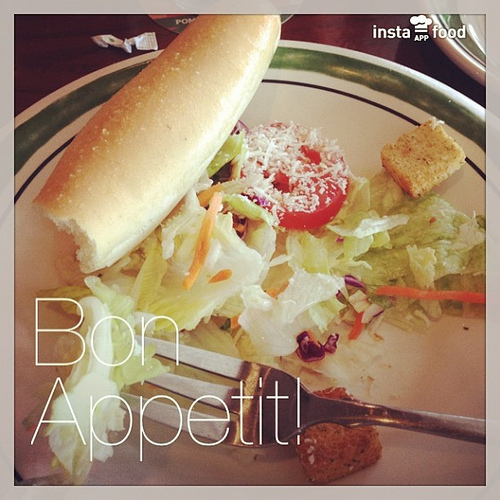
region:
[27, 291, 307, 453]
words written in white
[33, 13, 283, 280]
bread stick on a plate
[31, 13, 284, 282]
partially eaten bread stick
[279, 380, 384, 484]
crouton under a fork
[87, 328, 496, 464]
fork on a plate of food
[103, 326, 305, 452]
three tines of a fork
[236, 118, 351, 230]
tomato covered with cheese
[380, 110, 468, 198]
crouton on edge of dish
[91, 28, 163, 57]
straw wrapper on the table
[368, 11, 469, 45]
logo for an app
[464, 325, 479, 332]
part of a plate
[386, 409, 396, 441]
edge of a plate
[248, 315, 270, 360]
part of a fork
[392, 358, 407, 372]
part of a plate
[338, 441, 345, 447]
part of a cake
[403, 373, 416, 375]
part of a plate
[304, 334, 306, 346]
part of a vegetable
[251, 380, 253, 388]
part of a fork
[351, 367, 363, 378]
part of a plate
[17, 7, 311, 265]
bread stick has a bite taken out of it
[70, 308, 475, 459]
fork has three tines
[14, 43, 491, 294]
plate has a thin green strip and a thick one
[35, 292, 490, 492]
fork is laying across the plate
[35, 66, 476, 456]
salad is half eaten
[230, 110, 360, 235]
sliced tomato is covered with cheese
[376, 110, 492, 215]
crouton is shaped like a square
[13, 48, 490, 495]
plate is white with green stripe around it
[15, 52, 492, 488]
plate has food on it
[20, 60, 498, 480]
salad on plate has been eaten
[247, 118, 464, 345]
A salad is on the plate.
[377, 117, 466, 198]
The salad contains croutons.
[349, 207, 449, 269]
The salad contains lettuce.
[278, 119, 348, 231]
The salad contains tomatoes.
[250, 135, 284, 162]
The salad contains cheese.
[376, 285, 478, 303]
The salad contains carrots.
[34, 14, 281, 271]
A piece of bread is on the plate.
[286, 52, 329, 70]
The plate is green.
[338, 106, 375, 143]
The plate is white.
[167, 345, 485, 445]
A fork is on the plate.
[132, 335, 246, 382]
the prong of a silver fork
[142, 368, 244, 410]
the prong of a silver fork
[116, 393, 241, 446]
the prong of a silver fork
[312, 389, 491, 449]
the handle of the silver fork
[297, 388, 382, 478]
a square tan crouton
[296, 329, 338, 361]
a piece of purple cabbage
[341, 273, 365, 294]
a piece of purple cabbage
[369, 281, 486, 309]
a piece of carrot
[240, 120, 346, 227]
a piece of tomato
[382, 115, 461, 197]
a brown crouton